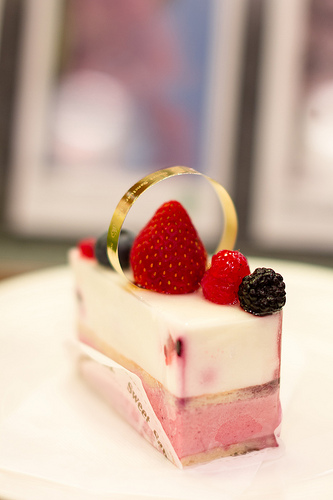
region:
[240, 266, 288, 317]
a blackberry on a cake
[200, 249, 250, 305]
a raspberry on a cake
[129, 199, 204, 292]
a red strawberry on a cake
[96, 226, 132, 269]
a blueberry on a cake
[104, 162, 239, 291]
a gold colored ring on a cake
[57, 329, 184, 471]
the paper wrapper of the cake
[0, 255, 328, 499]
the white table the cake is on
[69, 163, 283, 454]
a pink cake with berries on it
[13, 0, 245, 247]
a framed picture in the background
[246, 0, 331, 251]
a framed photo in the background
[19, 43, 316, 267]
the background is blurry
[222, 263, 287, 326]
a blackberry on the cake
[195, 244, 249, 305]
a raspberry on the cake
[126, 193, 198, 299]
a strawberry on the cake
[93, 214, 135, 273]
a blueberry on the cake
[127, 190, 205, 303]
the strawberry has seeds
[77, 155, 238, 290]
a gold ring on the cake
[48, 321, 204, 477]
paper under the cake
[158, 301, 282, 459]
4 layers to the cake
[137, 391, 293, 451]
pink layer in the cake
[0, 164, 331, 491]
Square dessert on white plate.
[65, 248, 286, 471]
Dessert with four layers.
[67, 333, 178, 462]
White paper with 'Sweet' written on it.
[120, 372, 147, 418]
'Sweet' written in gold.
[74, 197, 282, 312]
Five pieces of fruit on top of dessert.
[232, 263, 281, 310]
Blackberry on top of dessert.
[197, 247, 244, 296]
Raspberry on top of dessert.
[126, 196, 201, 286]
Strawberry on top of dessert.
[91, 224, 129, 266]
Blueberry on top of dessert.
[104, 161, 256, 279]
Gold band on top of dessert.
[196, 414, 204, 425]
edge of an ice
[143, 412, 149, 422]
part of a paper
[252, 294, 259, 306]
part of a cherry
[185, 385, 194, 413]
edge of an ice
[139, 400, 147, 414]
edge of a paper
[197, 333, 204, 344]
part of an ice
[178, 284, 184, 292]
part of a cherry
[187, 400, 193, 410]
edge of a surfacen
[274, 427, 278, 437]
side of an ice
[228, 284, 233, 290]
part of a cherry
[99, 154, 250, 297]
a wedding band on a cake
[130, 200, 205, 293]
a nice red strawberry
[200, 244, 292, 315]
One raspberry and one black berry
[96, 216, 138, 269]
a blue berry on the other side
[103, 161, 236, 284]
a ring with engravings on it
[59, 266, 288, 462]
a white and pink piece of cake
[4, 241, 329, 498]
a round white plate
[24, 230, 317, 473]
a piece of cake on a plate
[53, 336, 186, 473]
a white wrapping under cake with word sweet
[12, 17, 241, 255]
a blurry photo in a frame